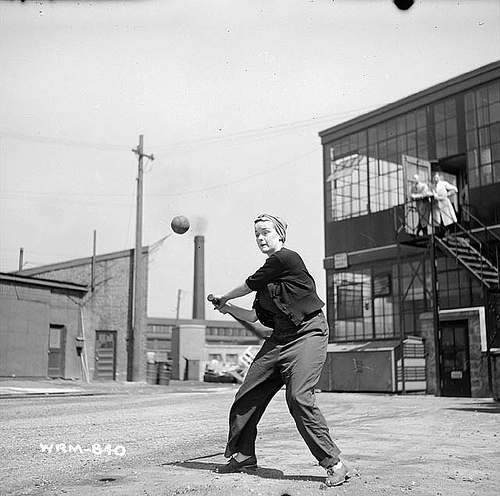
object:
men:
[408, 172, 432, 237]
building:
[317, 59, 500, 401]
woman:
[210, 211, 353, 487]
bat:
[206, 293, 274, 342]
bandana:
[253, 212, 289, 244]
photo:
[0, 0, 500, 496]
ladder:
[432, 234, 499, 290]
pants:
[222, 307, 342, 471]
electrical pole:
[129, 133, 155, 383]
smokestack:
[192, 235, 206, 321]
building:
[146, 316, 274, 382]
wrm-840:
[39, 442, 127, 458]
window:
[324, 153, 364, 183]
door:
[401, 153, 434, 236]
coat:
[425, 179, 459, 228]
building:
[0, 245, 150, 382]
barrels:
[144, 359, 158, 385]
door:
[93, 328, 118, 380]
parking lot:
[0, 377, 499, 495]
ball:
[170, 214, 191, 235]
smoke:
[190, 214, 208, 238]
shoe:
[214, 455, 258, 474]